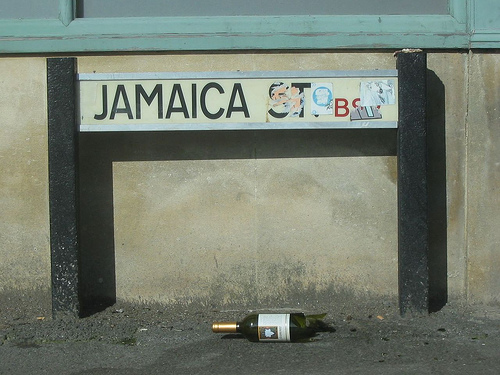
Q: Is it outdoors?
A: Yes, it is outdoors.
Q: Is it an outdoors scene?
A: Yes, it is outdoors.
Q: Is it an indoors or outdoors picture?
A: It is outdoors.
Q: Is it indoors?
A: No, it is outdoors.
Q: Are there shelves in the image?
A: No, there are no shelves.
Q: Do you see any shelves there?
A: No, there are no shelves.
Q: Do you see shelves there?
A: No, there are no shelves.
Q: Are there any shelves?
A: No, there are no shelves.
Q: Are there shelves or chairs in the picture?
A: No, there are no shelves or chairs.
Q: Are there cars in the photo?
A: No, there are no cars.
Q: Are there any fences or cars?
A: No, there are no cars or fences.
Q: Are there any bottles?
A: Yes, there is a bottle.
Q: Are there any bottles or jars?
A: Yes, there is a bottle.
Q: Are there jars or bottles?
A: Yes, there is a bottle.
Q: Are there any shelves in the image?
A: No, there are no shelves.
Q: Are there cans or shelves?
A: No, there are no shelves or cans.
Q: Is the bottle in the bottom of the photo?
A: Yes, the bottle is in the bottom of the image.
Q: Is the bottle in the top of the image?
A: No, the bottle is in the bottom of the image.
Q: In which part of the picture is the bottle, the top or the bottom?
A: The bottle is in the bottom of the image.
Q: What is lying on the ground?
A: The bottle is lying on the ground.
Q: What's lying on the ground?
A: The bottle is lying on the ground.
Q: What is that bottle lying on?
A: The bottle is lying on the ground.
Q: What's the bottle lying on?
A: The bottle is lying on the ground.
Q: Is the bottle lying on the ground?
A: Yes, the bottle is lying on the ground.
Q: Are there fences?
A: No, there are no fences.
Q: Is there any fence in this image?
A: No, there are no fences.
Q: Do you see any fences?
A: No, there are no fences.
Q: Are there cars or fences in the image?
A: No, there are no fences or cars.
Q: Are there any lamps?
A: No, there are no lamps.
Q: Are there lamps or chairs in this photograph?
A: No, there are no lamps or chairs.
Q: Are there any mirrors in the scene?
A: No, there are no mirrors.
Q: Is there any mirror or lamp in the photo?
A: No, there are no mirrors or lamps.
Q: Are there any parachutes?
A: No, there are no parachutes.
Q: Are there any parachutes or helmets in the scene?
A: No, there are no parachutes or helmets.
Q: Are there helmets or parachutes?
A: No, there are no parachutes or helmets.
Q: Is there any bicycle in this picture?
A: No, there are no bicycles.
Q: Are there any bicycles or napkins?
A: No, there are no bicycles or napkins.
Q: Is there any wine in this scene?
A: Yes, there is wine.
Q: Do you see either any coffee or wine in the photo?
A: Yes, there is wine.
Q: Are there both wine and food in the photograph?
A: No, there is wine but no food.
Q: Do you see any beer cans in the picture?
A: No, there are no beer cans.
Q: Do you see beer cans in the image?
A: No, there are no beer cans.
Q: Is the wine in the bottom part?
A: Yes, the wine is in the bottom of the image.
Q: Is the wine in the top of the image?
A: No, the wine is in the bottom of the image.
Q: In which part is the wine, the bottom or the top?
A: The wine is in the bottom of the image.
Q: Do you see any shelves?
A: No, there are no shelves.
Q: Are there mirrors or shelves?
A: No, there are no shelves or mirrors.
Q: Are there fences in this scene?
A: No, there are no fences.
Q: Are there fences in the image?
A: No, there are no fences.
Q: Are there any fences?
A: No, there are no fences.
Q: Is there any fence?
A: No, there are no fences.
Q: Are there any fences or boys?
A: No, there are no fences or boys.